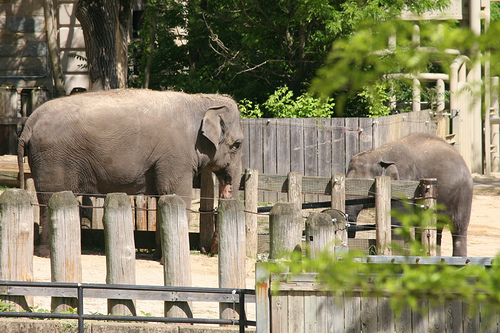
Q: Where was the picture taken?
A: It was taken at the zoo.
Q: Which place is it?
A: It is a zoo.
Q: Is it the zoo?
A: Yes, it is the zoo.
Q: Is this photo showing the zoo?
A: Yes, it is showing the zoo.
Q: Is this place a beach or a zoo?
A: It is a zoo.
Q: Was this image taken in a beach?
A: No, the picture was taken in a zoo.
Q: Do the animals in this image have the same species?
A: Yes, all the animals are elephants.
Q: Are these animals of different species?
A: No, all the animals are elephants.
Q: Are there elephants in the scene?
A: Yes, there is an elephant.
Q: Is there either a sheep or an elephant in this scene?
A: Yes, there is an elephant.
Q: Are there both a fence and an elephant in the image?
A: Yes, there are both an elephant and a fence.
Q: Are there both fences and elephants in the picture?
A: Yes, there are both an elephant and a fence.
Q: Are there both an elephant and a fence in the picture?
A: Yes, there are both an elephant and a fence.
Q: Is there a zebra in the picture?
A: No, there are no zebras.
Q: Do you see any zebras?
A: No, there are no zebras.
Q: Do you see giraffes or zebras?
A: No, there are no zebras or giraffes.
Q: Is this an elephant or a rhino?
A: This is an elephant.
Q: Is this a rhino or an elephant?
A: This is an elephant.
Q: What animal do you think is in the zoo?
A: The elephant is in the zoo.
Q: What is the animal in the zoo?
A: The animal is an elephant.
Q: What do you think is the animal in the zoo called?
A: The animal is an elephant.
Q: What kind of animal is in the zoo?
A: The animal is an elephant.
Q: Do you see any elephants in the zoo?
A: Yes, there is an elephant in the zoo.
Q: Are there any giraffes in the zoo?
A: No, there is an elephant in the zoo.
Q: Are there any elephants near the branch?
A: Yes, there is an elephant near the branch.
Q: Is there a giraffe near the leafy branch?
A: No, there is an elephant near the branch.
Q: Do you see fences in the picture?
A: Yes, there is a fence.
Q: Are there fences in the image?
A: Yes, there is a fence.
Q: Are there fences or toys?
A: Yes, there is a fence.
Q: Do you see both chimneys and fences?
A: No, there is a fence but no chimneys.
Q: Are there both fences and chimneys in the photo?
A: No, there is a fence but no chimneys.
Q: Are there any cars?
A: No, there are no cars.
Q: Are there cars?
A: No, there are no cars.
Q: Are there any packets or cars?
A: No, there are no cars or packets.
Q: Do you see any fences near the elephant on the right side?
A: Yes, there is a fence near the elephant.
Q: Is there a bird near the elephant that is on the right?
A: No, there is a fence near the elephant.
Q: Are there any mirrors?
A: No, there are no mirrors.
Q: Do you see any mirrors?
A: No, there are no mirrors.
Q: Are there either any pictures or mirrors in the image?
A: No, there are no mirrors or pictures.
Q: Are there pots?
A: No, there are no pots.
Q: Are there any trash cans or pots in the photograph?
A: No, there are no pots or trash cans.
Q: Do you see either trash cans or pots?
A: No, there are no pots or trash cans.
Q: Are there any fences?
A: Yes, there is a fence.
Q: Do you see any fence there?
A: Yes, there is a fence.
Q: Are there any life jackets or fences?
A: Yes, there is a fence.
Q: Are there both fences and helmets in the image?
A: No, there is a fence but no helmets.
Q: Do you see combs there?
A: No, there are no combs.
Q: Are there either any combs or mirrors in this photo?
A: No, there are no combs or mirrors.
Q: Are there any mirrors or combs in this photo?
A: No, there are no combs or mirrors.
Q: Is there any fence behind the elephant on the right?
A: Yes, there is a fence behind the elephant.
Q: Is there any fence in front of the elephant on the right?
A: No, the fence is behind the elephant.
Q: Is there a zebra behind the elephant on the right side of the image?
A: No, there is a fence behind the elephant.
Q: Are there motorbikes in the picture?
A: No, there are no motorbikes.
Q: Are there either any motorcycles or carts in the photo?
A: No, there are no motorcycles or carts.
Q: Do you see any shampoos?
A: No, there are no shampoos.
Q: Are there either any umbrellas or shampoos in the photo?
A: No, there are no shampoos or umbrellas.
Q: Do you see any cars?
A: No, there are no cars.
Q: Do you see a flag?
A: No, there are no flags.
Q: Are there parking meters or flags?
A: No, there are no flags or parking meters.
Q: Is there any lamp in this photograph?
A: No, there are no lamps.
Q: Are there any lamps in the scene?
A: No, there are no lamps.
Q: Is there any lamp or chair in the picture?
A: No, there are no lamps or chairs.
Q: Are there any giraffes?
A: No, there are no giraffes.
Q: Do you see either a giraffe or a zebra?
A: No, there are no giraffes or zebras.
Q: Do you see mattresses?
A: No, there are no mattresses.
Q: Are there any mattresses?
A: No, there are no mattresses.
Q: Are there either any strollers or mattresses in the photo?
A: No, there are no mattresses or strollers.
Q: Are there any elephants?
A: Yes, there is an elephant.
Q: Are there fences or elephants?
A: Yes, there is an elephant.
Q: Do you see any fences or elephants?
A: Yes, there is an elephant.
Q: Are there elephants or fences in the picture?
A: Yes, there is an elephant.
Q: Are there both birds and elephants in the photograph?
A: No, there is an elephant but no birds.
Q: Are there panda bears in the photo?
A: No, there are no panda bears.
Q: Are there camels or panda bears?
A: No, there are no panda bears or camels.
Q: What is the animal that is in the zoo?
A: The animal is an elephant.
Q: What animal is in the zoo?
A: The animal is an elephant.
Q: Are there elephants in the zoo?
A: Yes, there is an elephant in the zoo.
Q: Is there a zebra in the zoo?
A: No, there is an elephant in the zoo.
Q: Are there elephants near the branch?
A: Yes, there is an elephant near the branch.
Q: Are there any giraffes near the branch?
A: No, there is an elephant near the branch.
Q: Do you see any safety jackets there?
A: No, there are no safety jackets.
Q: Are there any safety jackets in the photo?
A: No, there are no safety jackets.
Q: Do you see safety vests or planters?
A: No, there are no safety vests or planters.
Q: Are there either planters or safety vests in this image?
A: No, there are no safety vests or planters.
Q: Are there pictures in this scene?
A: No, there are no pictures.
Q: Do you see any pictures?
A: No, there are no pictures.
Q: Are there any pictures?
A: No, there are no pictures.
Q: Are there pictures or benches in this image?
A: No, there are no pictures or benches.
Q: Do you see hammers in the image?
A: No, there are no hammers.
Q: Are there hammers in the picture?
A: No, there are no hammers.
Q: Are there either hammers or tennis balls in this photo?
A: No, there are no hammers or tennis balls.